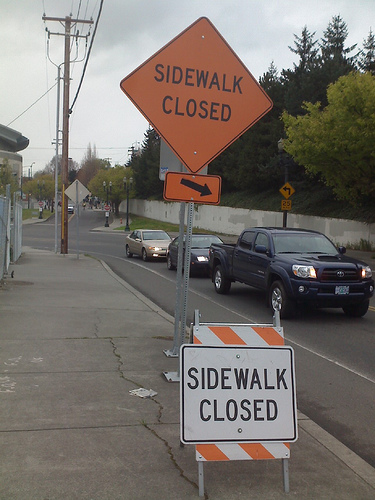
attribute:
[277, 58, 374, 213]
tree — green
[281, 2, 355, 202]
tree — green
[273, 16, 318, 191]
tree — green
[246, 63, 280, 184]
tree — green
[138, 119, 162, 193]
tree — green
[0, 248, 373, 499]
sidewalk — grey, cracked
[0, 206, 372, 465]
road — grey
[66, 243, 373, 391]
line — white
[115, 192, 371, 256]
wall — white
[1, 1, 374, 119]
air — grey, cloudy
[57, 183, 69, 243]
board — brown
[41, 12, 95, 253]
pole — brown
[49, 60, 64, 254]
pole — grey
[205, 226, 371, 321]
car — blue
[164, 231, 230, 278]
car — black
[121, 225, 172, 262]
car — tan, beige, last, brown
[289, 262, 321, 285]
lights — on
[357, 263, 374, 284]
lights — on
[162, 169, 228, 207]
sign — orange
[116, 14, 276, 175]
sign — orange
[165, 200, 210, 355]
pole — grey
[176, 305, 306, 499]
sign — orange, white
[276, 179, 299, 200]
sign — yellow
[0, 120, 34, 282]
house — white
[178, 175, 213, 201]
arrow — black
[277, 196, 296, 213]
sign — yellow